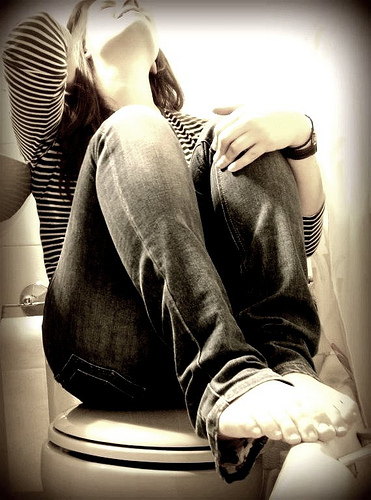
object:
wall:
[0, 0, 78, 318]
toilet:
[39, 403, 370, 498]